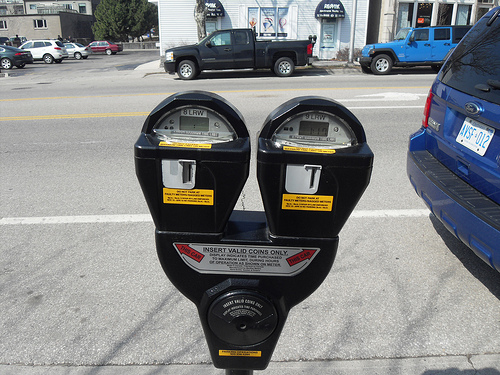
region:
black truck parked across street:
[158, 24, 334, 76]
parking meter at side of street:
[124, 86, 381, 373]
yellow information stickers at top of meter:
[155, 136, 343, 218]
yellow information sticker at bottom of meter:
[213, 346, 268, 363]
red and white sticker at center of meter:
[167, 235, 329, 283]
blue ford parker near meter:
[405, 3, 498, 269]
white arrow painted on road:
[306, 78, 438, 115]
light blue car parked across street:
[355, 19, 483, 71]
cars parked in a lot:
[0, 27, 125, 74]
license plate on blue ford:
[454, 107, 497, 165]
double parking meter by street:
[111, 85, 348, 374]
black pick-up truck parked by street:
[148, 21, 328, 80]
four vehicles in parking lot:
[3, 16, 130, 70]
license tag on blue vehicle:
[443, 95, 498, 181]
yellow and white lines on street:
[4, 87, 414, 237]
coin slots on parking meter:
[163, 154, 337, 201]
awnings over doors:
[185, 2, 370, 27]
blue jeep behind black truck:
[160, 18, 474, 75]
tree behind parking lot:
[83, 3, 173, 51]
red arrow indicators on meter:
[157, 233, 330, 281]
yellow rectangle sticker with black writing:
[163, 186, 213, 204]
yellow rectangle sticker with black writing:
[280, 194, 333, 210]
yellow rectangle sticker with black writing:
[218, 347, 263, 357]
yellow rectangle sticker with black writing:
[159, 139, 212, 148]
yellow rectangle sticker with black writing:
[283, 144, 338, 153]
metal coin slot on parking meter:
[161, 159, 197, 185]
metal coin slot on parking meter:
[286, 164, 321, 194]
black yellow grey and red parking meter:
[128, 87, 365, 370]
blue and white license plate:
[452, 113, 494, 155]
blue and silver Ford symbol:
[461, 99, 479, 113]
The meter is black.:
[120, 101, 383, 373]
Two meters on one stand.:
[133, 63, 366, 252]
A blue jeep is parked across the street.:
[368, 23, 498, 75]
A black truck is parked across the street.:
[164, 34, 331, 76]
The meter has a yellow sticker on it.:
[280, 188, 334, 224]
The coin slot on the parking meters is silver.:
[162, 158, 329, 191]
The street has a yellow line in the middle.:
[31, 101, 171, 127]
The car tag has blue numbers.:
[452, 105, 495, 155]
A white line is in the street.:
[17, 197, 421, 227]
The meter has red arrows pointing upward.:
[163, 236, 320, 276]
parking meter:
[132, 89, 377, 374]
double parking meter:
[122, 87, 374, 373]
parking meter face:
[147, 91, 242, 152]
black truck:
[160, 23, 340, 81]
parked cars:
[0, 30, 127, 73]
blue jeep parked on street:
[360, 25, 462, 76]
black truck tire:
[166, 55, 208, 81]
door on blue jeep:
[405, 21, 452, 61]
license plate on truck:
[453, 112, 498, 162]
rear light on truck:
[300, 40, 315, 63]